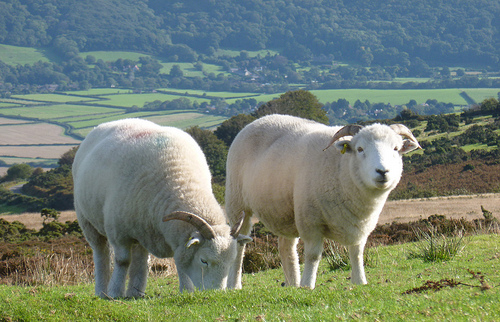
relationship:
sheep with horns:
[55, 94, 427, 299] [162, 203, 256, 249]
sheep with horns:
[55, 94, 427, 299] [318, 107, 424, 160]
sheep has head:
[55, 94, 427, 299] [334, 107, 414, 202]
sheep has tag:
[55, 94, 427, 299] [338, 135, 350, 161]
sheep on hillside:
[55, 94, 427, 299] [0, 160, 499, 320]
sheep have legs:
[55, 94, 427, 299] [216, 224, 380, 298]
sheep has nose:
[55, 94, 427, 299] [377, 166, 392, 176]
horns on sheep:
[162, 203, 256, 249] [55, 94, 427, 299]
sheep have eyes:
[55, 94, 427, 299] [352, 142, 405, 156]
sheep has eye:
[55, 94, 427, 299] [194, 257, 211, 268]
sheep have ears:
[55, 94, 427, 299] [334, 137, 418, 152]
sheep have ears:
[55, 94, 427, 299] [181, 237, 258, 247]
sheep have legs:
[55, 94, 427, 299] [86, 227, 171, 301]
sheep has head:
[55, 94, 427, 299] [169, 217, 248, 298]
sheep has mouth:
[55, 94, 427, 299] [374, 178, 392, 187]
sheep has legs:
[55, 94, 427, 299] [216, 224, 380, 298]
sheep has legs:
[55, 94, 427, 299] [86, 227, 171, 301]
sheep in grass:
[55, 94, 427, 299] [2, 221, 499, 322]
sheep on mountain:
[55, 94, 427, 299] [0, 160, 499, 320]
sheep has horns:
[55, 94, 427, 299] [162, 203, 256, 249]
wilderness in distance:
[0, 1, 498, 90] [1, 2, 498, 116]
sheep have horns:
[55, 94, 427, 299] [162, 203, 256, 249]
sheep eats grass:
[72, 113, 423, 298] [2, 221, 499, 322]